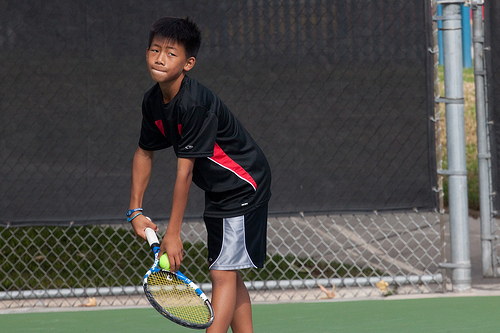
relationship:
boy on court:
[125, 15, 271, 332] [1, 287, 480, 331]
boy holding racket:
[125, 15, 271, 332] [115, 191, 225, 329]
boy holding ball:
[125, 15, 271, 332] [154, 244, 179, 275]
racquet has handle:
[139, 210, 218, 331] [144, 211, 162, 247]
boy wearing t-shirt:
[125, 15, 271, 332] [139, 89, 279, 217]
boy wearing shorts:
[125, 15, 271, 332] [204, 200, 268, 269]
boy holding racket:
[125, 15, 271, 332] [137, 210, 215, 330]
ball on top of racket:
[158, 252, 170, 270] [131, 207, 219, 330]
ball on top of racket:
[158, 252, 170, 270] [126, 297, 220, 331]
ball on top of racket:
[158, 252, 170, 270] [135, 216, 205, 330]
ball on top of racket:
[158, 252, 170, 270] [143, 223, 223, 331]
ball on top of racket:
[158, 252, 170, 270] [143, 268, 213, 327]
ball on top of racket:
[158, 252, 170, 270] [141, 226, 211, 328]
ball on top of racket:
[158, 252, 170, 270] [140, 218, 214, 330]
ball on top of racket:
[158, 252, 170, 270] [119, 214, 266, 331]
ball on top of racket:
[158, 252, 170, 270] [144, 214, 212, 328]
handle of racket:
[124, 205, 169, 245] [127, 213, 223, 330]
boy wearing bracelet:
[125, 15, 271, 332] [123, 208, 143, 215]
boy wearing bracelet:
[125, 15, 271, 332] [125, 211, 142, 223]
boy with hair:
[112, 14, 302, 273] [148, 16, 205, 46]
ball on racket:
[159, 250, 174, 271] [137, 210, 215, 330]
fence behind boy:
[3, 2, 498, 316] [125, 15, 271, 332]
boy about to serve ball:
[125, 15, 271, 332] [157, 248, 173, 275]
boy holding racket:
[125, 15, 271, 332] [128, 211, 216, 328]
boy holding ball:
[125, 15, 271, 332] [159, 250, 171, 272]